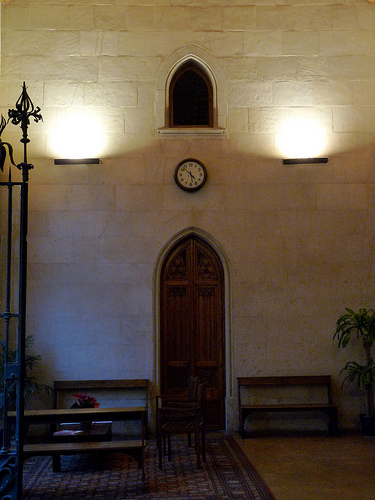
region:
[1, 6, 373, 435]
building with white walls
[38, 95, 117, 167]
light on left side of building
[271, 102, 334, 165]
lights on right side of building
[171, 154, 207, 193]
a clock on top of a door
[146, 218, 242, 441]
door has is in an arch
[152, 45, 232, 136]
window on top of the clock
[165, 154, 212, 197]
the clock has brawn frame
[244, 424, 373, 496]
floor of building is light brown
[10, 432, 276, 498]
carpet is on floor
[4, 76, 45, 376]
pointy stick on left side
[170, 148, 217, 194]
black and white clock on wall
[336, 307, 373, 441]
potted plant with green leaves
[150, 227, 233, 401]
large brown wooden door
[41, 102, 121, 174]
light on side of wall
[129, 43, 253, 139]
window on wall above door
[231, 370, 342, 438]
brown wooden bench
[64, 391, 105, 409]
plant with red flowers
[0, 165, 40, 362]
black metal fencing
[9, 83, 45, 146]
design on top of black fencing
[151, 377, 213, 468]
brown wooden chair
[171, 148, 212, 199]
A clock is on the wall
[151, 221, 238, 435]
There is a wooden door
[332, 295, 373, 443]
A green plant sits in the corner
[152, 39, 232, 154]
There is a window above the door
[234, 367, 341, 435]
A bench is next to the door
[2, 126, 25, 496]
A metal gate on the side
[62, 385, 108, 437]
an orange plant on a table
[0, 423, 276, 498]
a rug on the floor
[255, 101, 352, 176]
Bright white light fixture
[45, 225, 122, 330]
white tile walls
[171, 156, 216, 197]
black and white clock above door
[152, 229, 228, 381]
large wooden brown door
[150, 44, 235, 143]
window above door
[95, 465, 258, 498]
rug with designs on floor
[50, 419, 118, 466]
brown table with magazines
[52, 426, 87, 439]
magazine laying on table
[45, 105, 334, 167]
Two lights.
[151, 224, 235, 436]
Closed brown wooden door.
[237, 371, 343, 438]
Wooden bench.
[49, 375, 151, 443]
Brown wooden bench to the left of the door.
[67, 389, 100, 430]
Pointsettia plant.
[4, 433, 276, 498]
Rug laying on the floor.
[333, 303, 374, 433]
Potted plant.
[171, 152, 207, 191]
Clock hanging on the wall.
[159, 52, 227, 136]
Window with an arched top.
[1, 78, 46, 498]
Metal gate with sharp points at the top.